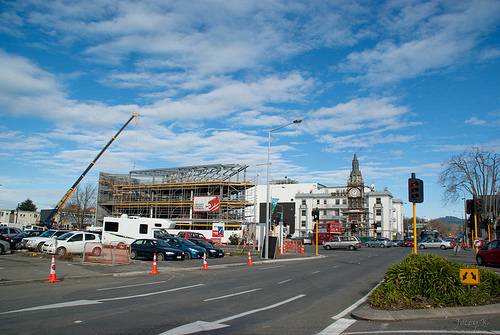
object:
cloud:
[463, 115, 488, 126]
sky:
[0, 0, 499, 222]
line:
[203, 287, 264, 301]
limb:
[492, 154, 498, 181]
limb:
[453, 180, 470, 185]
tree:
[438, 143, 500, 254]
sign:
[457, 266, 479, 285]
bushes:
[365, 252, 499, 310]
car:
[323, 233, 361, 251]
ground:
[0, 247, 499, 334]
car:
[187, 238, 225, 259]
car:
[162, 236, 209, 259]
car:
[127, 238, 185, 261]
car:
[20, 229, 73, 251]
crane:
[36, 112, 141, 227]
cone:
[44, 254, 63, 282]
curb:
[0, 273, 114, 286]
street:
[0, 243, 500, 335]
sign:
[408, 177, 424, 203]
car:
[40, 231, 102, 254]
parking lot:
[0, 228, 244, 280]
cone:
[149, 253, 159, 275]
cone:
[200, 250, 210, 270]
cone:
[300, 244, 305, 253]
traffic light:
[407, 178, 424, 204]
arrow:
[157, 293, 308, 333]